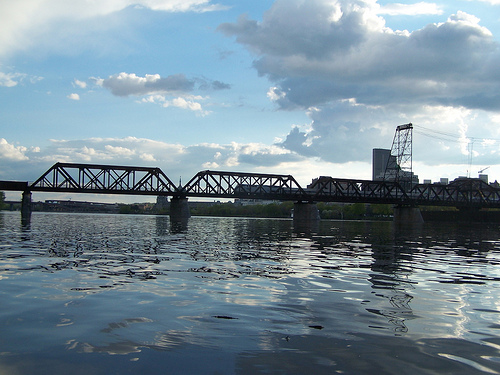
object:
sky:
[0, 0, 499, 187]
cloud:
[302, 38, 390, 115]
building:
[369, 149, 419, 193]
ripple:
[245, 236, 308, 308]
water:
[145, 223, 391, 339]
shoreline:
[0, 207, 388, 250]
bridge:
[0, 161, 500, 210]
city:
[370, 147, 500, 202]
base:
[170, 198, 191, 221]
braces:
[293, 200, 324, 233]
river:
[197, 275, 440, 373]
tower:
[381, 121, 416, 189]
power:
[412, 123, 499, 146]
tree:
[314, 203, 420, 220]